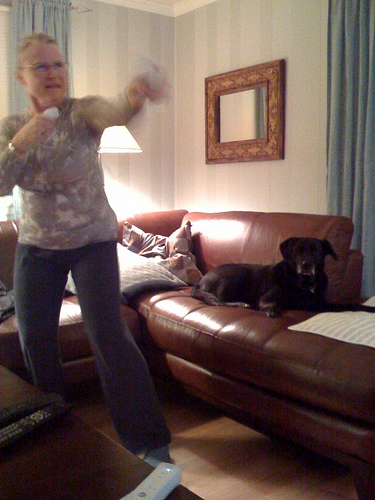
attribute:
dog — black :
[187, 235, 324, 312]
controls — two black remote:
[40, 59, 168, 145]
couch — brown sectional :
[114, 198, 362, 444]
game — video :
[35, 59, 165, 142]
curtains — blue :
[7, 2, 99, 208]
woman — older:
[2, 20, 184, 470]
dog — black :
[198, 229, 331, 312]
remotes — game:
[18, 63, 161, 124]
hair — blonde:
[12, 29, 59, 72]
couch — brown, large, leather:
[1, 207, 363, 498]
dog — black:
[188, 234, 363, 317]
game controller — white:
[117, 459, 181, 498]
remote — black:
[1, 388, 64, 425]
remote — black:
[1, 398, 74, 451]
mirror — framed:
[203, 57, 286, 163]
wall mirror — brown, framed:
[203, 57, 286, 162]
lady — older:
[0, 30, 174, 468]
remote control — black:
[1, 390, 63, 426]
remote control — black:
[1, 398, 71, 451]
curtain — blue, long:
[323, 0, 363, 297]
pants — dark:
[12, 238, 172, 453]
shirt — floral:
[0, 96, 143, 250]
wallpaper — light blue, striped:
[71, 1, 329, 216]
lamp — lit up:
[96, 124, 142, 185]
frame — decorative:
[203, 57, 286, 165]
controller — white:
[110, 458, 191, 498]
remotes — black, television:
[0, 385, 72, 457]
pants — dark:
[16, 237, 183, 457]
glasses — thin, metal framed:
[18, 55, 69, 77]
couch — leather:
[116, 201, 373, 471]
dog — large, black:
[190, 229, 365, 330]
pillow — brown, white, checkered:
[115, 217, 209, 286]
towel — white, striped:
[297, 308, 373, 357]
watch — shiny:
[6, 139, 28, 160]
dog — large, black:
[193, 231, 373, 316]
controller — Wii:
[132, 53, 174, 104]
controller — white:
[132, 53, 183, 134]